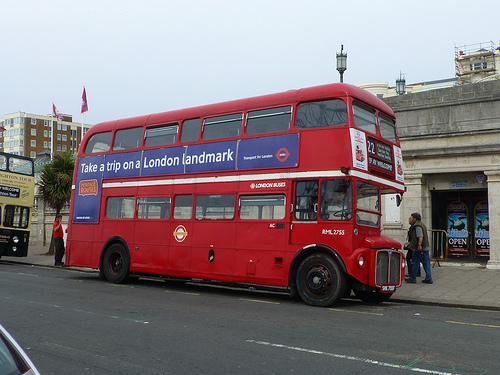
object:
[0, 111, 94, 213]
building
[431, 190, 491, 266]
door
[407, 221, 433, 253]
shirt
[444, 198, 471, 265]
signs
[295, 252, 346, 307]
front tire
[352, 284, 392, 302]
front tire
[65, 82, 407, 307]
bus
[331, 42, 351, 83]
light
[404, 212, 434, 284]
man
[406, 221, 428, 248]
jacket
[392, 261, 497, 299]
sidewalk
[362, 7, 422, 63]
clouds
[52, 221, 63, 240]
shirt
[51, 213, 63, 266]
man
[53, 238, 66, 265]
pants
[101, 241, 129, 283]
tire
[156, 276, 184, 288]
tire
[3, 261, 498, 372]
road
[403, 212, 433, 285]
people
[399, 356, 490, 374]
green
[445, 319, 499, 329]
yellowline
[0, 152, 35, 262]
bus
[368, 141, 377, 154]
22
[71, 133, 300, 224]
sign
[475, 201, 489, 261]
signs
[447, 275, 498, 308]
brick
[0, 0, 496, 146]
sky